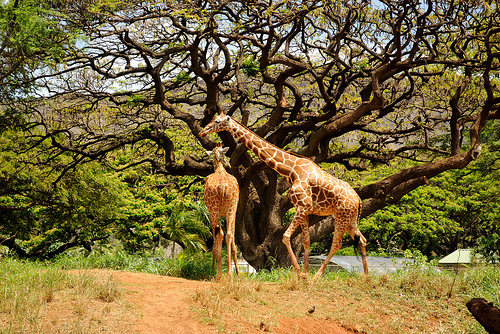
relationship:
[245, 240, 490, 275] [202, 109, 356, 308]
fence around giraffes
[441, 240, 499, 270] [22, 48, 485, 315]
buildings outside enclosure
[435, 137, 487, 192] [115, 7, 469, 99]
wound on branches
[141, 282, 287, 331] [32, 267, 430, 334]
dirt on ground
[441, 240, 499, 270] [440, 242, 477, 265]
buildings have roofs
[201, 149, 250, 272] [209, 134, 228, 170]
giraffe has head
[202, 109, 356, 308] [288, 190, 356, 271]
giraffes have legs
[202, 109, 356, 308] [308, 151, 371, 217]
giraffes have backs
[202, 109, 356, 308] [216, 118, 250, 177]
giraffes have necks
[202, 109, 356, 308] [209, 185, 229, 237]
giraffes have tail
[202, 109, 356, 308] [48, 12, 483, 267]
giraffes near tree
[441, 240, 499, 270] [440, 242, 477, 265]
buildings have roof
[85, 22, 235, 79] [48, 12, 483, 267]
sky behind tree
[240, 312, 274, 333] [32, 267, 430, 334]
spot on ground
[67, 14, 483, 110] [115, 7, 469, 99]
lot of branches